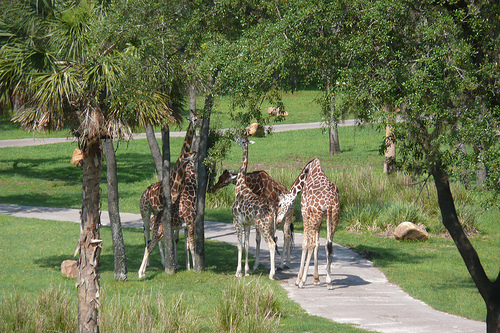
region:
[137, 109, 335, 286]
Group of giraffes walking on the sidewalk and grass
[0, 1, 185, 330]
Small tree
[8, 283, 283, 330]
Patch of light green bushes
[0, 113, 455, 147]
Sidewalk made of white cement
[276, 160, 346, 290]
Giraffe covered in sunlight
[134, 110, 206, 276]
Giraffe receiving shade from the trees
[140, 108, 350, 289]
The giraffes are wandering around the area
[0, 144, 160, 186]
Shadow of a tree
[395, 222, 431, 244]
Small tree bark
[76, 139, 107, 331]
Tree stem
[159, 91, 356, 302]
Giraffes eating leaves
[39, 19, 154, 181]
Palm tree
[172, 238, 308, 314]
Green grass in the giraffe's enclosure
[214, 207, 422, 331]
A cement trail through the giraffe's enclosure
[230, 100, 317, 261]
A giraffe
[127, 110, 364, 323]
Five giraffes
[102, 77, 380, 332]
Lots of giraffes at the zoo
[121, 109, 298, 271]
Lots of giraffes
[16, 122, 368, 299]
Giraffes grazing in their enclosure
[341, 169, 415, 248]
High grass in the field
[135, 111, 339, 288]
Giraffes standing underneath trees.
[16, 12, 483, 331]
Giraffes standing in a wildlife park.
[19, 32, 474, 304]
Five brown and white giraffes standing in the park.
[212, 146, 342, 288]
Two brown and white giraffes standing on the sidewalk.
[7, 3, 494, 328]
Giraffes standing under trees for shade.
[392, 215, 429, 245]
Rock on the ground of the park.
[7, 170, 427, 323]
Gray sidewalk with five giraffes standing.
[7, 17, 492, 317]
Wildlife with gray sidewalks.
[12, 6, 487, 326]
Wildlife park containing giraffes.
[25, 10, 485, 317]
Wild park with natural features.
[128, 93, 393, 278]
five giraffes on the field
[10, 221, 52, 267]
the grass is green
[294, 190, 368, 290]
the giraffe has tail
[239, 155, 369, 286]
the giraffe is smelling the other giraffe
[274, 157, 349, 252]
the giraffe is brown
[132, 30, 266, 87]
the leaves are green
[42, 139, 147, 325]
the trunk is brown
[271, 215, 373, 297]
the giraffe has four legs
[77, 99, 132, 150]
the leaves are dry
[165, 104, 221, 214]
the giraffes have long necks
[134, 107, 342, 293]
Five giraffes standing underneath trees with green leaves.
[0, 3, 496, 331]
Giraffes in a wildlife park standing underneath green trees.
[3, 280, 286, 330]
Green and brown brushes.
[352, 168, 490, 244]
Rock in front of landscape with bushes.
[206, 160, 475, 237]
Bushes in the landscaping.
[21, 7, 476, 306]
Brown and white giraffes standing near landscaping.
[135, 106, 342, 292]
Five giraffes standing between landscaping with bushes.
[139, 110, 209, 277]
Two giraffes under trees for shade.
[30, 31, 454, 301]
National wildlife park with brown and white zebras.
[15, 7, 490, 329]
National wildlife park with giraffes and beautiful landscaping.